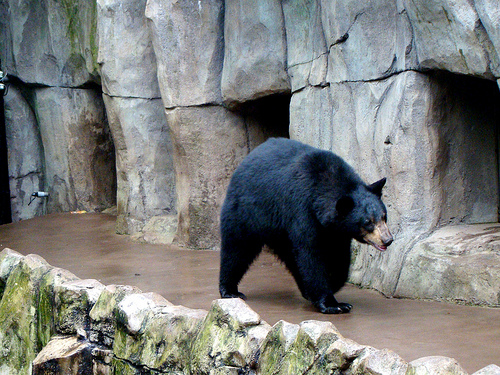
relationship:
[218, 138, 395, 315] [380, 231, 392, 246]
bear has nose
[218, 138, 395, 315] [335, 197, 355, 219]
bear has ear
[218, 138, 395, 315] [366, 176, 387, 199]
bear has ear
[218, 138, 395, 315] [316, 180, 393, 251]
bear has head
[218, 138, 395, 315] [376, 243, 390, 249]
bear has tongue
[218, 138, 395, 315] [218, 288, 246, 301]
bear has paw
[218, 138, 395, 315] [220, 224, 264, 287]
bear has leg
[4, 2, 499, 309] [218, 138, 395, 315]
wall next to bear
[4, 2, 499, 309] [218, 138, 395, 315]
wall behind bear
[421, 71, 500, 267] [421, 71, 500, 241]
cave has cave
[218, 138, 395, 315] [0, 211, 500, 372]
bear on top of pathway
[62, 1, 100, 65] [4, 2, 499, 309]
moss on wall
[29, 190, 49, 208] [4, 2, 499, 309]
camera attached to wall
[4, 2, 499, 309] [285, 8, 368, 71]
wall has crack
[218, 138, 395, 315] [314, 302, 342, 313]
bear has paw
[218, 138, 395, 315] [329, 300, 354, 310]
bear has paw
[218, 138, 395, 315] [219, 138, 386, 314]
bear has fur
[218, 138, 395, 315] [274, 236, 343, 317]
bear has leg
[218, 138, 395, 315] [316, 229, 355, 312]
bear has leg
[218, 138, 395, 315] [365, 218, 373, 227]
bear has eye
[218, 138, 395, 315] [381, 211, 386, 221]
bear has eye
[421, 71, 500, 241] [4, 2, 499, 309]
cave in wall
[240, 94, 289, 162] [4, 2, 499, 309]
opening in wall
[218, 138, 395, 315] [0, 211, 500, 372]
bear standing on pathway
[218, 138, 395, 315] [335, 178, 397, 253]
bear has face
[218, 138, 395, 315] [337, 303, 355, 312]
bear has claws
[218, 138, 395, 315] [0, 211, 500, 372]
bear walking on pathway